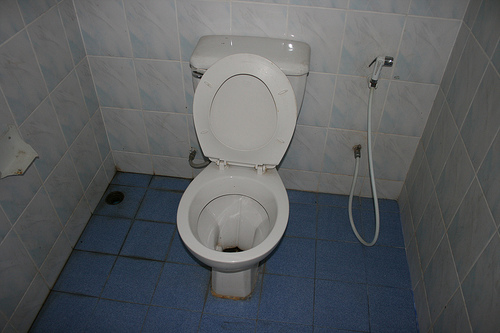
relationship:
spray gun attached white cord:
[367, 55, 395, 90] [347, 85, 382, 247]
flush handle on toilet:
[182, 59, 202, 83] [122, 9, 343, 290]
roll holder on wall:
[9, 119, 76, 191] [409, 95, 466, 225]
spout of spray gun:
[374, 48, 404, 79] [361, 52, 396, 92]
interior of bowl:
[203, 184, 303, 274] [205, 200, 257, 243]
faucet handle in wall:
[368, 56, 395, 89] [360, 36, 417, 203]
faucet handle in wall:
[368, 56, 395, 89] [350, 40, 420, 175]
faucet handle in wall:
[365, 50, 392, 94] [2, 3, 494, 332]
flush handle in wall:
[191, 70, 203, 79] [364, 37, 437, 223]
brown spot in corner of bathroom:
[104, 189, 124, 206] [1, 0, 498, 330]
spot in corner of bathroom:
[103, 188, 125, 206] [50, 30, 342, 330]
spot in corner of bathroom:
[350, 142, 363, 159] [59, 25, 463, 300]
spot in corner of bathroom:
[77, 160, 120, 225] [1, 0, 498, 330]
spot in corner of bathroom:
[206, 224, 247, 305] [22, 11, 471, 296]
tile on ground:
[32, 161, 423, 332] [361, 144, 380, 191]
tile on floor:
[32, 161, 423, 332] [322, 240, 425, 327]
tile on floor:
[313, 279, 368, 330] [322, 240, 425, 327]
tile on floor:
[32, 161, 423, 332] [320, 236, 420, 330]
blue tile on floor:
[313, 237, 367, 289] [287, 193, 387, 330]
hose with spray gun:
[340, 50, 398, 250] [367, 55, 395, 90]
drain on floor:
[99, 188, 128, 208] [308, 239, 417, 331]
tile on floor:
[32, 161, 423, 332] [25, 165, 417, 331]